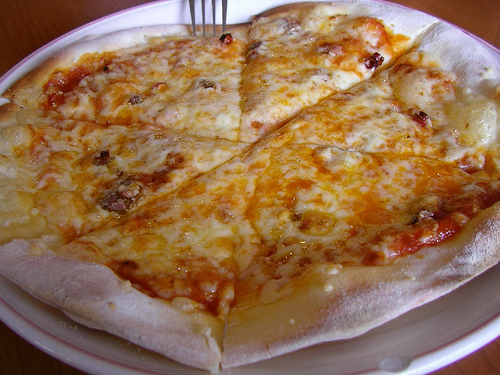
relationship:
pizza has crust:
[3, 2, 500, 369] [6, 244, 206, 350]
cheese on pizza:
[90, 93, 263, 211] [3, 2, 500, 369]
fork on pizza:
[184, 0, 228, 42] [3, 2, 500, 369]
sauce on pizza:
[397, 209, 459, 253] [3, 2, 500, 369]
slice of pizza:
[19, 8, 254, 144] [3, 2, 500, 369]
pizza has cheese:
[3, 2, 500, 369] [90, 93, 263, 211]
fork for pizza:
[184, 0, 228, 42] [3, 2, 500, 369]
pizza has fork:
[3, 2, 500, 369] [184, 0, 228, 42]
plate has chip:
[3, 2, 500, 369] [379, 352, 417, 369]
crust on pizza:
[6, 244, 206, 350] [3, 2, 500, 369]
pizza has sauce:
[3, 2, 500, 369] [397, 209, 459, 253]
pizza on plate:
[3, 2, 500, 369] [3, 2, 500, 369]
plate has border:
[3, 2, 500, 369] [6, 11, 171, 69]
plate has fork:
[3, 2, 500, 369] [184, 0, 228, 42]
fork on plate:
[184, 0, 228, 42] [3, 2, 500, 369]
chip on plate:
[379, 352, 417, 369] [3, 2, 500, 369]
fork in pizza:
[184, 0, 228, 42] [3, 2, 500, 369]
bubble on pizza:
[315, 142, 361, 179] [3, 2, 500, 369]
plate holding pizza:
[3, 2, 500, 369] [3, 2, 500, 369]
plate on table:
[3, 2, 500, 369] [0, 11, 489, 76]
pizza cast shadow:
[3, 2, 500, 369] [28, 279, 490, 365]